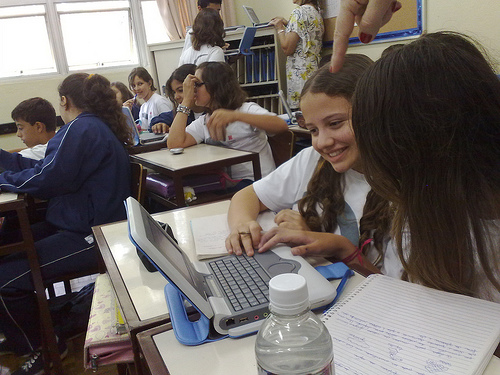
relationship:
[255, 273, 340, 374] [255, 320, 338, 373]
bottle of water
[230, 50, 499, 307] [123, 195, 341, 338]
girls working on a laptop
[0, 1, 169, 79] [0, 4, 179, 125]
windows on wall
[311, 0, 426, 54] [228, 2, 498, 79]
corkboard on wall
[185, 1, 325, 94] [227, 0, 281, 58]
people standing with laptops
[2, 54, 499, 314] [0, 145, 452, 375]
students sitting at desks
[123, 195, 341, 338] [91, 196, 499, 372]
laptop on table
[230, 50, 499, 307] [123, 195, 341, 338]
girls working on laptop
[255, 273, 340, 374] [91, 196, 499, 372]
bottle on table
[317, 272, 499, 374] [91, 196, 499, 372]
notebook on table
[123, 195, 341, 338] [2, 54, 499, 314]
laptop for children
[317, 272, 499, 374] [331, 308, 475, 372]
notebook with writing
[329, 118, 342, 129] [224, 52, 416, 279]
eye of girl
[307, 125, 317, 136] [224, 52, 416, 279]
eye of girl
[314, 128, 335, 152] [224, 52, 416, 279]
nose of girl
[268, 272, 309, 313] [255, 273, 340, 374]
lid of bottle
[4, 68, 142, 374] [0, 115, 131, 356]
girl wearing a tracksuit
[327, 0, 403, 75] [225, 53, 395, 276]
hand pointing at girl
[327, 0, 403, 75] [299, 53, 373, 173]
hand pointing at head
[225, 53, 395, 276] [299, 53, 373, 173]
girl has head